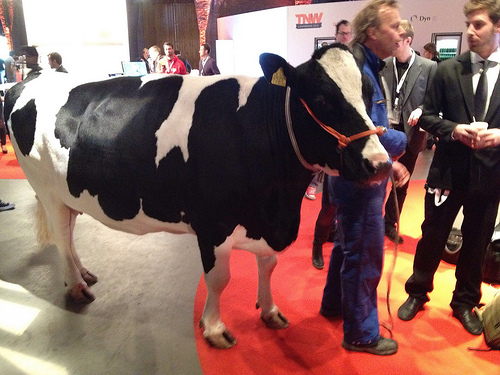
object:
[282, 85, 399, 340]
leash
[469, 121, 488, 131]
cup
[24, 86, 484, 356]
floor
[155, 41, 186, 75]
man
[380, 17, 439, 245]
man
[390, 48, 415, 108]
lanyard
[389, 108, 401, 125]
tag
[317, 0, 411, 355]
man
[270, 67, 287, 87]
tag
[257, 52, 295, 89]
ear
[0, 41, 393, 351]
cow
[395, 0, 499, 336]
man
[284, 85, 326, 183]
this is a belt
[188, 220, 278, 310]
legs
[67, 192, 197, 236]
belly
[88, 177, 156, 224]
belly is fat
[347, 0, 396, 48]
hair is long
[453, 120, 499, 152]
man holding coffee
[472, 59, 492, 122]
black tie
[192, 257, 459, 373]
red carpet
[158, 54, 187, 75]
red hoodie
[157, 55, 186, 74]
man wearing tag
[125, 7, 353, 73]
behind the men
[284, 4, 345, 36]
lettering on board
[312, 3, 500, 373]
group of people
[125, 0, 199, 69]
wood panels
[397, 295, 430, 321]
shoes on the man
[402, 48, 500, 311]
man in suit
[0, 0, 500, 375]
this picture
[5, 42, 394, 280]
black and white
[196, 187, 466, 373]
harness is orange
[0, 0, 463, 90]
background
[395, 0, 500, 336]
man looks inquisitiv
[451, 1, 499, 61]
looking at something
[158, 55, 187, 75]
red in color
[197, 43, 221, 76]
this is a man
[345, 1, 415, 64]
light skinned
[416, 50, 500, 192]
coat is black